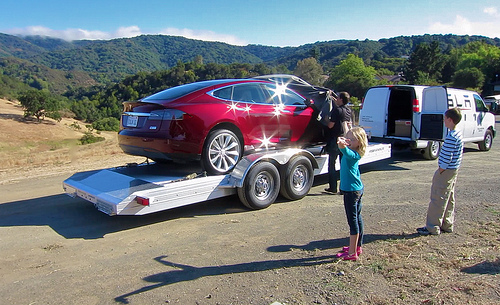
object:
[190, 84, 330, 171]
car side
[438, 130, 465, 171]
shirt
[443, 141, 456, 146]
stripes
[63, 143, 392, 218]
trailer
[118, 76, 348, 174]
car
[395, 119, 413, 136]
cardboard box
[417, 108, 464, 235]
boy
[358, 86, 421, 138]
back door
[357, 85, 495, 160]
truck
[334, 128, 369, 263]
girl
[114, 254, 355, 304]
shadow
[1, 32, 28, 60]
hill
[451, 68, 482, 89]
trees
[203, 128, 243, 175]
wheel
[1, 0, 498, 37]
sky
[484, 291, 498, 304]
grass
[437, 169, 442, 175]
hand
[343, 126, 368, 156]
hair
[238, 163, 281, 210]
tires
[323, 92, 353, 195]
man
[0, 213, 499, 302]
road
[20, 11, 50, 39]
clouds